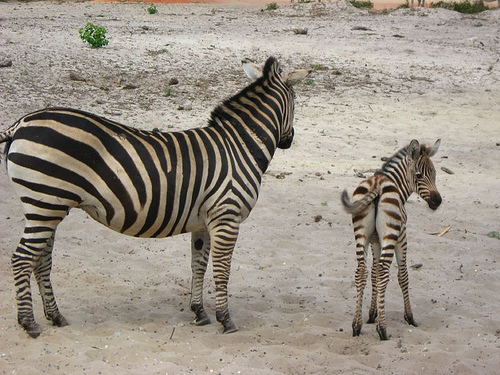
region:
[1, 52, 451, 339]
Two zebras in a sandy area.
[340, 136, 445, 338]
The little zebra is turning around.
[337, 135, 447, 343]
The young zebra's coat is white and brown striped.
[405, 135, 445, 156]
The young zebra's ears are pointing up.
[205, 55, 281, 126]
The zebra's mane is standing on the back of its neck.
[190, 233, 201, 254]
The adult zebra has a round dark spot under its left front leg.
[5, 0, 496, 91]
Sand is dirty.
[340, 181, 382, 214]
Young zebra with short tail.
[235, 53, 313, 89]
Adult zebra with ears pointing sideways.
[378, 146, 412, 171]
Young zebra with shorter mane on the back of its neck.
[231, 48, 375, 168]
the head of a zebra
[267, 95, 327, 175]
the mouth of a zebra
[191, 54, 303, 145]
the main of a zebra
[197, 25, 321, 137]
the ears of a zebra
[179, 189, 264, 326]
the front legs of a zebra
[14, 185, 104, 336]
the back legs of a zebra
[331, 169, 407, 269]
the tail of a zebra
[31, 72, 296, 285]
the body of a zebra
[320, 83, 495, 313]
a little baby zebra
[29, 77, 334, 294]
a black and white zebra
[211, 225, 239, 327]
the leg of a zebra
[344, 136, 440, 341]
a young zebra standing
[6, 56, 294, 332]
an older zebra standing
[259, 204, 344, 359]
lots of a sand on the ground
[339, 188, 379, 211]
the tail of a young zebra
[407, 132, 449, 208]
the head of a young zebra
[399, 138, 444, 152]
the ears of a young zebra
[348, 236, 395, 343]
the hind legs of a young zebra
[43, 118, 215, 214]
black and white stripes of a zebra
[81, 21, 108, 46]
a green plant in the sand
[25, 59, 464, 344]
two zebras on sand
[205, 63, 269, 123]
black and white mane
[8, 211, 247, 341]
black and white legs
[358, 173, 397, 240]
young zebra has short tail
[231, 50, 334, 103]
zebra has white ears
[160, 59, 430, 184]
brown and tan sand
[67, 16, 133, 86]
green bush on sand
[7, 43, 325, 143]
small rocks on sand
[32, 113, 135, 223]
thick stripes on rump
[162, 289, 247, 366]
zebra has black feet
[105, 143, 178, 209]
Black and white strips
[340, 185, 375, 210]
zebra waving its tail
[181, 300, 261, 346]
Zebra standing on sand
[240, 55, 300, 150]
zebra looking toward left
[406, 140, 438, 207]
Zebra looking toward right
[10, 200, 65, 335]
back legs of zebra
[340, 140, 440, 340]
small zebra standing straight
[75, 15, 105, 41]
small green plant at background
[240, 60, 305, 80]
Ears of taller zebra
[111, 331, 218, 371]
dry grey sand on shore